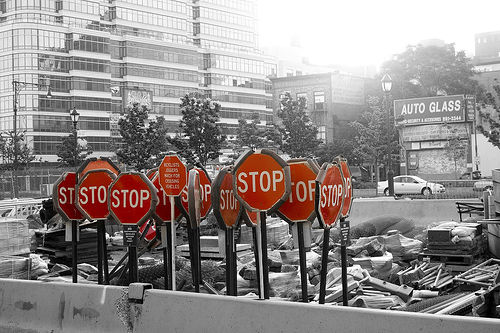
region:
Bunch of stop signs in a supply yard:
[48, 147, 358, 255]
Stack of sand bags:
[423, 214, 487, 261]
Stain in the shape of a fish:
[68, 300, 103, 322]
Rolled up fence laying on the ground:
[99, 252, 234, 294]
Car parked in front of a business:
[373, 165, 449, 199]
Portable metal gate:
[423, 175, 499, 204]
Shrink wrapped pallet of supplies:
[1, 213, 39, 287]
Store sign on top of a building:
[391, 96, 472, 126]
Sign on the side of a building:
[329, 72, 368, 108]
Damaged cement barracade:
[110, 278, 154, 332]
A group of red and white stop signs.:
[76, 185, 168, 201]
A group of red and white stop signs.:
[252, 247, 297, 259]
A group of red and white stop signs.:
[236, 304, 256, 313]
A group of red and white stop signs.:
[355, 308, 384, 327]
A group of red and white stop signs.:
[122, 256, 157, 305]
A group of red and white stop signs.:
[75, 308, 77, 329]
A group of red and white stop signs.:
[111, 310, 166, 323]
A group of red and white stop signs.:
[400, 207, 476, 208]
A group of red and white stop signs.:
[10, 310, 42, 326]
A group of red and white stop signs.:
[26, 234, 66, 243]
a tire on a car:
[416, 178, 434, 202]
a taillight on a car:
[370, 176, 383, 194]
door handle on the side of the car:
[399, 176, 407, 193]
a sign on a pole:
[468, 150, 487, 175]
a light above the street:
[59, 100, 82, 146]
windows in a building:
[38, 16, 76, 73]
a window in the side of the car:
[396, 165, 416, 187]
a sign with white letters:
[231, 149, 303, 223]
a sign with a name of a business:
[393, 85, 486, 135]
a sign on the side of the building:
[324, 63, 372, 118]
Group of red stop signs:
[49, 149, 352, 307]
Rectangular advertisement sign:
[392, 94, 466, 126]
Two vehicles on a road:
[376, 171, 493, 196]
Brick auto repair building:
[393, 93, 498, 185]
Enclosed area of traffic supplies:
[0, 152, 498, 331]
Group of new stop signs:
[48, 145, 354, 307]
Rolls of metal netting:
[112, 253, 221, 291]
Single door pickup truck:
[440, 170, 495, 186]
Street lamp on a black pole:
[379, 72, 394, 196]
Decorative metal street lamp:
[9, 77, 53, 167]